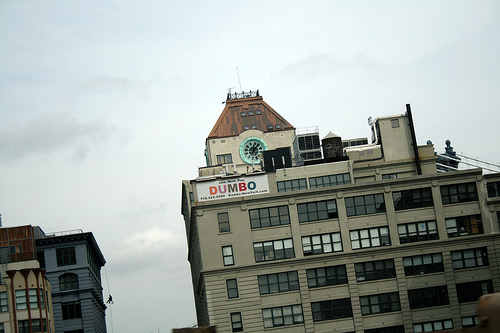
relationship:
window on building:
[220, 240, 237, 265] [181, 103, 443, 328]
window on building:
[225, 280, 237, 300] [179, 85, 496, 331]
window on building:
[307, 262, 350, 287] [179, 85, 496, 331]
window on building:
[329, 262, 360, 277] [179, 85, 496, 331]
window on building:
[229, 309, 245, 329] [158, 108, 499, 320]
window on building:
[58, 273, 79, 289] [0, 225, 110, 332]